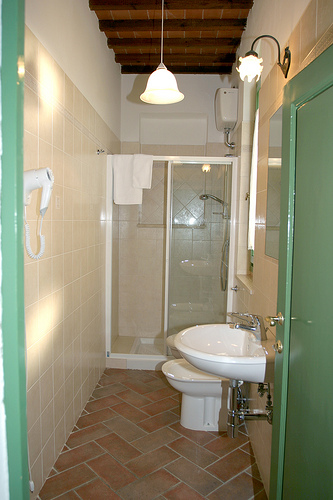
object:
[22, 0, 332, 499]
bathroom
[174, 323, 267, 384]
sink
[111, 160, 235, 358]
shower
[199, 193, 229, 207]
head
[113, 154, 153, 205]
towels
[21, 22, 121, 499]
wall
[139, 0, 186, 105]
fixture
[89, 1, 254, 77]
roof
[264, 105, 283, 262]
mirror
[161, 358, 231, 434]
toilet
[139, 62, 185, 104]
white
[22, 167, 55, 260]
white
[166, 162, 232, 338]
glass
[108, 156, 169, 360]
frame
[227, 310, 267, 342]
faucet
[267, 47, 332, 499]
green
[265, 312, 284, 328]
silver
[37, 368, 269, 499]
floor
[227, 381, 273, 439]
pipes